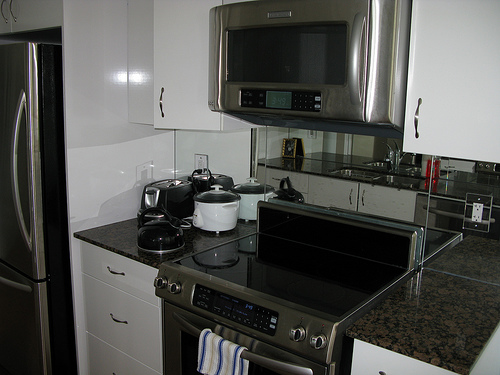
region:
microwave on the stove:
[208, 25, 345, 82]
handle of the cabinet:
[150, 75, 174, 127]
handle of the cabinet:
[405, 95, 431, 137]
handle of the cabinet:
[104, 261, 140, 283]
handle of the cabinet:
[95, 306, 127, 326]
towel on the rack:
[181, 320, 251, 369]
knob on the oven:
[315, 333, 325, 353]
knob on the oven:
[283, 324, 310, 339]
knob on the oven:
[172, 287, 182, 297]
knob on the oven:
[155, 269, 169, 286]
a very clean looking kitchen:
[8, 12, 496, 374]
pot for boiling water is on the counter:
[133, 205, 190, 257]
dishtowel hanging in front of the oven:
[187, 320, 256, 373]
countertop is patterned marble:
[344, 261, 494, 373]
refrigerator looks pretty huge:
[1, 44, 80, 371]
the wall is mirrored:
[248, 126, 498, 281]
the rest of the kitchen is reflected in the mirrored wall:
[256, 130, 496, 237]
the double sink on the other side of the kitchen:
[322, 155, 427, 197]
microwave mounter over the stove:
[203, 1, 409, 139]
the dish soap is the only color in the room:
[421, 154, 445, 184]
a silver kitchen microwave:
[190, 16, 412, 114]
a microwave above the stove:
[185, 9, 460, 349]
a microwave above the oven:
[171, 10, 465, 359]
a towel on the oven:
[162, 289, 277, 371]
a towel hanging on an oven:
[177, 296, 236, 368]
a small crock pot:
[179, 188, 242, 231]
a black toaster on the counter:
[150, 160, 190, 217]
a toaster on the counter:
[92, 153, 239, 225]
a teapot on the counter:
[121, 194, 179, 283]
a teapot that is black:
[135, 194, 239, 283]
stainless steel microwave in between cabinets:
[188, 0, 405, 148]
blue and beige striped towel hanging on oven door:
[183, 327, 249, 372]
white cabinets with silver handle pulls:
[77, 248, 153, 367]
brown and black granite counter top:
[361, 261, 456, 345]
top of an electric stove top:
[180, 235, 415, 331]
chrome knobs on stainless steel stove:
[285, 322, 331, 358]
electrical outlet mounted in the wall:
[456, 187, 496, 247]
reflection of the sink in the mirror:
[260, 132, 472, 242]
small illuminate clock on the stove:
[238, 300, 256, 309]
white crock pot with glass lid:
[189, 177, 254, 238]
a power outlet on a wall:
[451, 162, 498, 260]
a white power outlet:
[458, 171, 495, 246]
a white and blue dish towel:
[155, 287, 252, 374]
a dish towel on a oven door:
[146, 262, 269, 373]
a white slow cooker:
[171, 147, 253, 243]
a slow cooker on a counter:
[156, 171, 289, 281]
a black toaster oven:
[117, 167, 237, 238]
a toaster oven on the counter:
[105, 145, 214, 225]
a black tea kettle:
[123, 195, 203, 275]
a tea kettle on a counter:
[113, 207, 203, 271]